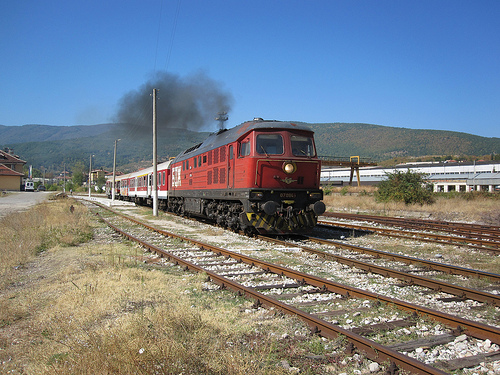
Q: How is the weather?
A: It is clear.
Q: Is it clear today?
A: Yes, it is clear.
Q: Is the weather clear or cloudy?
A: It is clear.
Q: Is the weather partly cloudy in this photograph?
A: No, it is clear.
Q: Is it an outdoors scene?
A: Yes, it is outdoors.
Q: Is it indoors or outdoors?
A: It is outdoors.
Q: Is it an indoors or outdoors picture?
A: It is outdoors.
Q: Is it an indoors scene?
A: No, it is outdoors.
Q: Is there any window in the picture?
A: Yes, there is a window.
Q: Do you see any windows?
A: Yes, there is a window.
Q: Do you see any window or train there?
A: Yes, there is a window.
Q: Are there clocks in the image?
A: No, there are no clocks.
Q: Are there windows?
A: Yes, there is a window.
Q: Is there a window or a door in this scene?
A: Yes, there is a window.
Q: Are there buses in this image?
A: No, there are no buses.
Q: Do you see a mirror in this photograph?
A: No, there are no mirrors.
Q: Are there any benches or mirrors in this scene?
A: No, there are no mirrors or benches.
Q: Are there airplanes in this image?
A: No, there are no airplanes.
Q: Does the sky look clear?
A: Yes, the sky is clear.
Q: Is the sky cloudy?
A: No, the sky is clear.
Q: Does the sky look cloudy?
A: No, the sky is clear.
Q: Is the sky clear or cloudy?
A: The sky is clear.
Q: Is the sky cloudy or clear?
A: The sky is clear.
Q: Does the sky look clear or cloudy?
A: The sky is clear.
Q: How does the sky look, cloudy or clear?
A: The sky is clear.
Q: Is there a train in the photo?
A: Yes, there is a train.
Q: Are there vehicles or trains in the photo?
A: Yes, there is a train.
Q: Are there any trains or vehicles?
A: Yes, there is a train.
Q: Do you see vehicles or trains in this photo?
A: Yes, there is a train.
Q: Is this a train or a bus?
A: This is a train.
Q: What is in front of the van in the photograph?
A: The train is in front of the van.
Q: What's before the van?
A: The train is in front of the van.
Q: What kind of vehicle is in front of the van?
A: The vehicle is a train.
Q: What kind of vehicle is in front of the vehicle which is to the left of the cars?
A: The vehicle is a train.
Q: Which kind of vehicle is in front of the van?
A: The vehicle is a train.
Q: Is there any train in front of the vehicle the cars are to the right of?
A: Yes, there is a train in front of the van.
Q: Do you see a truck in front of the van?
A: No, there is a train in front of the van.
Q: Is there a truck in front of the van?
A: No, there is a train in front of the van.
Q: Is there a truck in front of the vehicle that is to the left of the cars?
A: No, there is a train in front of the van.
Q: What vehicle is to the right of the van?
A: The vehicle is a train.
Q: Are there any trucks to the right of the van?
A: No, there is a train to the right of the van.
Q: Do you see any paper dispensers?
A: No, there are no paper dispensers.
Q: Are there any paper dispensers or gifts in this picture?
A: No, there are no paper dispensers or gifts.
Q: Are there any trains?
A: Yes, there is a train.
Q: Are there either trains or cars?
A: Yes, there is a train.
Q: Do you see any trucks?
A: No, there are no trucks.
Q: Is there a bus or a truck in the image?
A: No, there are no trucks or buses.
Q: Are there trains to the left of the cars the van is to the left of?
A: No, the train is to the right of the cars.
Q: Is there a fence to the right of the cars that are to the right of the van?
A: No, there is a train to the right of the cars.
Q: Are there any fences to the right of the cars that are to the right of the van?
A: No, there is a train to the right of the cars.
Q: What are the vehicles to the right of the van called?
A: The vehicles are cars.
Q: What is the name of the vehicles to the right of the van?
A: The vehicles are cars.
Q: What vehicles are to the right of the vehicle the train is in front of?
A: The vehicles are cars.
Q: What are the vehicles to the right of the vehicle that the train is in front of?
A: The vehicles are cars.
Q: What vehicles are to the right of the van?
A: The vehicles are cars.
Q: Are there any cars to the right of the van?
A: Yes, there are cars to the right of the van.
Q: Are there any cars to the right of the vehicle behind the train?
A: Yes, there are cars to the right of the van.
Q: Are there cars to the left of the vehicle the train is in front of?
A: No, the cars are to the right of the van.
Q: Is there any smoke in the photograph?
A: Yes, there is smoke.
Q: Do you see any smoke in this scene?
A: Yes, there is smoke.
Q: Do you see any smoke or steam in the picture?
A: Yes, there is smoke.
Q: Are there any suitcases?
A: No, there are no suitcases.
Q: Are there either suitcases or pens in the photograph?
A: No, there are no suitcases or pens.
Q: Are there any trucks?
A: No, there are no trucks.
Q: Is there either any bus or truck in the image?
A: No, there are no trucks or buses.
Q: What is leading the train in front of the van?
A: The car is leading the train.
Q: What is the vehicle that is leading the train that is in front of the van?
A: The vehicle is a car.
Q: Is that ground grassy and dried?
A: Yes, the ground is grassy and dried.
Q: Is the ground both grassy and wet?
A: No, the ground is grassy but dried.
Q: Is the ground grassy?
A: Yes, the ground is grassy.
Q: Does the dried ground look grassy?
A: Yes, the ground is grassy.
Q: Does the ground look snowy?
A: No, the ground is grassy.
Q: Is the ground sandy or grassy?
A: The ground is grassy.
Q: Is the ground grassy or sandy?
A: The ground is grassy.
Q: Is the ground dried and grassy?
A: Yes, the ground is dried and grassy.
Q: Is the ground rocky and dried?
A: No, the ground is dried but grassy.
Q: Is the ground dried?
A: Yes, the ground is dried.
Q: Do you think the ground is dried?
A: Yes, the ground is dried.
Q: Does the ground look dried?
A: Yes, the ground is dried.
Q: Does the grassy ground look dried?
A: Yes, the ground is dried.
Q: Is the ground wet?
A: No, the ground is dried.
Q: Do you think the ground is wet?
A: No, the ground is dried.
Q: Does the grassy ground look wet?
A: No, the ground is dried.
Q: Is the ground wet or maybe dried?
A: The ground is dried.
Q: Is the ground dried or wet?
A: The ground is dried.